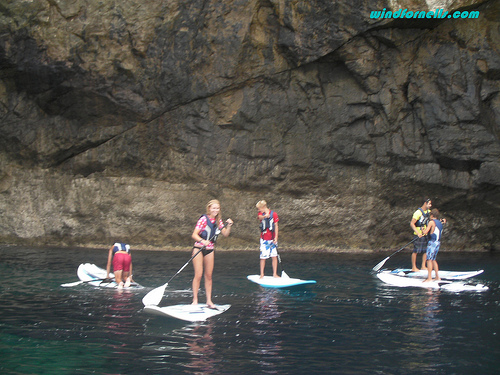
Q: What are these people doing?
A: Paddleboarding.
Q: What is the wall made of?
A: Rock.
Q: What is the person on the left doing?
A: On her knees.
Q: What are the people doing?
A: Paddle boarding.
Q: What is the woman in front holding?
A: A paddle.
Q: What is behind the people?
A: A rock wall.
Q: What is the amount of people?
A: Five.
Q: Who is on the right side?
A: Two guys.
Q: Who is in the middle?
A: A boy with a red shirt.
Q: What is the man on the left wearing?
A: Swim trunks and a life jacket.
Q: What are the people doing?
A: Wakeboarding.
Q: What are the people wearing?
A: Lifevest.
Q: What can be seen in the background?
A: A rockwall.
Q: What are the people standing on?
A: Surfboards.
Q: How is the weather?
A: Sunny.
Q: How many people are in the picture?
A: Five.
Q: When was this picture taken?
A: Daytime.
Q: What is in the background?
A: A cliff.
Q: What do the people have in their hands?
A: Paddles.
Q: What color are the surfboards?
A: White.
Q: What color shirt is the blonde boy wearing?
A: Red.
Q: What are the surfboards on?
A: Water.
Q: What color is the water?
A: Black.